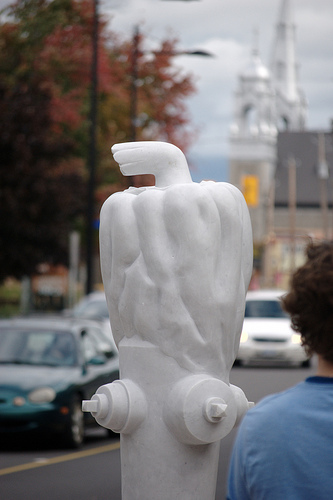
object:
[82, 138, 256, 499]
hydrant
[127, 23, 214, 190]
lamp post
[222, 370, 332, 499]
t-shirt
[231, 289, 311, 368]
car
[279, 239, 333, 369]
head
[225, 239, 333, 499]
person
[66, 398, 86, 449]
tire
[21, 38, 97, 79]
leaves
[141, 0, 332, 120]
cloud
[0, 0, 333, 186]
sky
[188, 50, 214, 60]
street light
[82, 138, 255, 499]
sculpture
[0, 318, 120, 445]
car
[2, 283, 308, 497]
street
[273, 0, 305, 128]
steeple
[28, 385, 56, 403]
headlight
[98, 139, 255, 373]
top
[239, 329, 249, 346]
car/lights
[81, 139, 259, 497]
white post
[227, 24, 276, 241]
tower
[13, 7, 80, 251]
tree